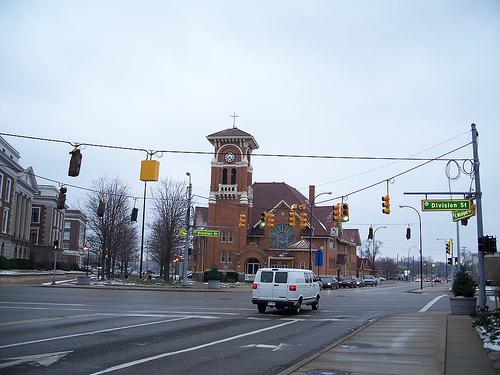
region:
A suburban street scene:
[2, 5, 497, 373]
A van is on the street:
[246, 265, 326, 316]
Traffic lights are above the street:
[234, 193, 396, 233]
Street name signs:
[402, 187, 484, 225]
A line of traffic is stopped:
[321, 270, 382, 292]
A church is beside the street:
[184, 108, 363, 282]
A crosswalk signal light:
[475, 232, 498, 256]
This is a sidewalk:
[270, 308, 497, 373]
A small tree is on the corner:
[448, 263, 480, 318]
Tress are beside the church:
[83, 176, 193, 283]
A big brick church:
[190, 109, 380, 281]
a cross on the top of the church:
[227, 110, 239, 127]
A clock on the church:
[224, 150, 235, 161]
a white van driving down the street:
[252, 267, 319, 309]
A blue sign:
[313, 247, 321, 276]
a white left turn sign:
[330, 225, 338, 236]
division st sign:
[421, 201, 471, 211]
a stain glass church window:
[270, 222, 296, 250]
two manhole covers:
[307, 333, 372, 373]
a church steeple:
[207, 111, 254, 205]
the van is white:
[230, 240, 372, 343]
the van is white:
[241, 251, 328, 325]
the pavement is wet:
[64, 285, 126, 332]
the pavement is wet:
[339, 295, 364, 312]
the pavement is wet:
[108, 307, 188, 363]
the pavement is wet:
[151, 260, 216, 322]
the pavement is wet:
[346, 277, 407, 305]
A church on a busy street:
[191, 113, 379, 282]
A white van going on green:
[244, 185, 399, 334]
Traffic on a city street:
[258, 200, 415, 317]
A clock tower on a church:
[203, 143, 255, 288]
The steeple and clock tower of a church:
[204, 107, 254, 277]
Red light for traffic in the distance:
[408, 260, 455, 287]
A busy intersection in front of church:
[142, 148, 478, 333]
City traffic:
[246, 254, 449, 314]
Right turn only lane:
[227, 317, 318, 372]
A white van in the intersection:
[249, 262, 328, 324]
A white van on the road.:
[239, 263, 328, 318]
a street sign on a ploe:
[420, 186, 478, 216]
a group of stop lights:
[235, 189, 402, 239]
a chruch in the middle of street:
[189, 115, 351, 278]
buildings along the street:
[6, 139, 111, 281]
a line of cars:
[327, 271, 384, 291]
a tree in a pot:
[450, 261, 486, 316]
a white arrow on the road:
[239, 331, 308, 353]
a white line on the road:
[414, 286, 449, 316]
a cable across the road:
[349, 143, 443, 317]